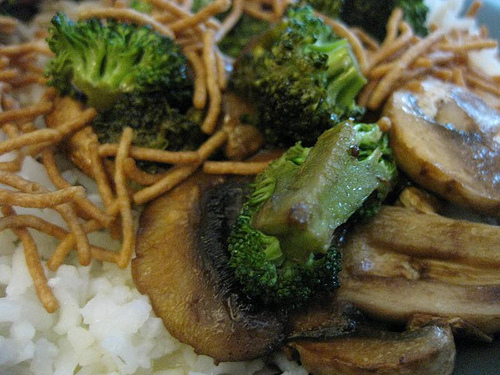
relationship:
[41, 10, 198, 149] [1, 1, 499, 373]
broccoli on rice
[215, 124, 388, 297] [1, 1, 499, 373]
broccoli on rice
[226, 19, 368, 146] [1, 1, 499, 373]
broccoli on rice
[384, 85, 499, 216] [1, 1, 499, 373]
mushroom on rice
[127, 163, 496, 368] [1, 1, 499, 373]
mushroom on rice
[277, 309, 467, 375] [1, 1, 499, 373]
mushroom on rice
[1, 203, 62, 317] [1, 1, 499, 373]
noodle on rice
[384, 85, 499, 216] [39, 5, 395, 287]
mushroom near broccoli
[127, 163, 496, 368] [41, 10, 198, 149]
mushroom mixed with broccoli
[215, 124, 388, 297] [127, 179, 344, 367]
broccoli on top of zucchini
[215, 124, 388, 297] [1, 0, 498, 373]
broccoli on top of meal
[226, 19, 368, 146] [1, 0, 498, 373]
broccoli on top of meal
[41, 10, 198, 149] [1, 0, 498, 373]
broccoli on top of meal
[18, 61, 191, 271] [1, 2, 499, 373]
fried noodles on top of entree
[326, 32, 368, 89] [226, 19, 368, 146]
stem on broccoli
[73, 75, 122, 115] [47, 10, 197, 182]
stem on broccoli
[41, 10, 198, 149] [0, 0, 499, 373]
broccoli on plate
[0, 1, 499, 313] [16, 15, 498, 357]
topping on dish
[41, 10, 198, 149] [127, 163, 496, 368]
broccoli on top of mushroom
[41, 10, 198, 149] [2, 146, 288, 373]
broccoli on top of rice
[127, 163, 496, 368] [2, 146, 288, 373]
mushroom on top of rice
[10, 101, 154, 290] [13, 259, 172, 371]
topping on top of rice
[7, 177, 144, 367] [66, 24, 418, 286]
rice under vegetable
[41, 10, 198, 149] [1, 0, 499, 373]
broccoli on top of dish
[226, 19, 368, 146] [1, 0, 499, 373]
broccoli on top of dish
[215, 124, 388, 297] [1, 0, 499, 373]
broccoli on top of dish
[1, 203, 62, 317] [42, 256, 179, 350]
noodle on top of rice